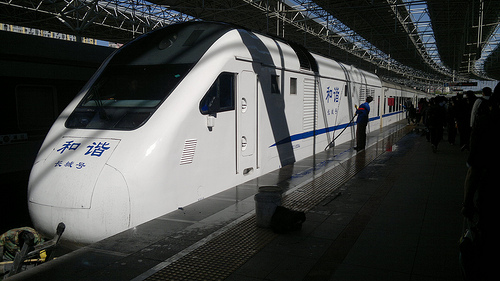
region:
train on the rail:
[20, 18, 409, 211]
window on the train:
[94, 62, 166, 104]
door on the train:
[238, 64, 259, 155]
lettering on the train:
[43, 131, 106, 173]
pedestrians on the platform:
[411, 73, 484, 145]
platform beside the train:
[335, 165, 424, 272]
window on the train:
[268, 73, 279, 94]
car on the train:
[66, 36, 386, 170]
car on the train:
[379, 79, 424, 127]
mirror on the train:
[206, 105, 223, 133]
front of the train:
[0, 25, 237, 248]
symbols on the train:
[47, 117, 137, 177]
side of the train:
[206, 57, 356, 147]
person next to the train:
[331, 80, 392, 165]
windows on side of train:
[367, 76, 424, 128]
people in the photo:
[410, 77, 485, 142]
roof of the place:
[331, 9, 450, 69]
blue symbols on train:
[30, 121, 122, 194]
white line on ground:
[182, 186, 269, 268]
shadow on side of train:
[257, 88, 312, 145]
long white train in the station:
[24, 34, 407, 197]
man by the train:
[339, 84, 373, 169]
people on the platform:
[416, 75, 496, 153]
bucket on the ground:
[245, 181, 280, 231]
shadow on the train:
[233, 52, 305, 172]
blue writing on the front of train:
[48, 138, 128, 163]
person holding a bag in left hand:
[456, 205, 481, 274]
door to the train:
[228, 67, 255, 175]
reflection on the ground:
[342, 158, 380, 173]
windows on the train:
[390, 100, 407, 114]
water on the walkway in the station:
[35, 145, 431, 280]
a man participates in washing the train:
[316, 87, 371, 157]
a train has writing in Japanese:
[50, 135, 105, 175]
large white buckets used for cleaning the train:
[250, 175, 290, 230]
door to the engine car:
[232, 65, 253, 171]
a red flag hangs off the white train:
[385, 93, 397, 108]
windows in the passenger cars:
[385, 95, 425, 110]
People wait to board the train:
[412, 85, 497, 227]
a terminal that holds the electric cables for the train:
[272, 0, 322, 37]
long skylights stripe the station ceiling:
[279, 0, 463, 88]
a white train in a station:
[22, 23, 433, 245]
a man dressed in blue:
[347, 89, 378, 156]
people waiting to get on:
[404, 82, 494, 257]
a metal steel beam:
[291, 38, 436, 66]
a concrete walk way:
[337, 143, 454, 247]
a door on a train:
[232, 63, 257, 178]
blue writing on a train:
[44, 136, 108, 174]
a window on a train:
[79, 59, 181, 131]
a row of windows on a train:
[387, 98, 404, 113]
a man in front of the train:
[4, 218, 58, 268]